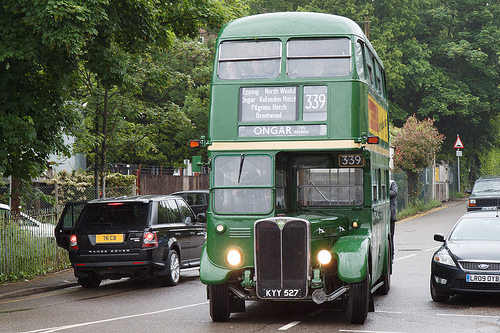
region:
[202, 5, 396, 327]
The double decker bus is green.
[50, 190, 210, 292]
The Range Rover to the left of the bus has its door open.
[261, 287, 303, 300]
The plate on the grill of the bus has the letters KYY 527 on it.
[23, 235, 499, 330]
White lines are painted on the wet pavement.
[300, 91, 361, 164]
The numbers 339 can be seen on the front of the bus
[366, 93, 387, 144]
A yellow sign is painted on the upper level of the side of the bus.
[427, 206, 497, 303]
The car to the right of the bus is black.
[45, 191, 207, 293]
The SUV to the left of the bus is black.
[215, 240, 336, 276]
The bus has its headlights turned on.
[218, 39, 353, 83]
Passengers can be faintly seen through the second level windows of the bus.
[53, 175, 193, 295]
Black sport utility vehicle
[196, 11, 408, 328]
Green double decker bus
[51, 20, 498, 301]
Traffic on a street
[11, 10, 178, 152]
Tall green trees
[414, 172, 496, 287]
Line of vehicles in traffic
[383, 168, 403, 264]
Person standing in street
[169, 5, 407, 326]
Green bus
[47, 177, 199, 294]
Parked SUV with door open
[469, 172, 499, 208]
SUV in traffic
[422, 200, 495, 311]
Black car in traffic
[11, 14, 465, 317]
a large double decker bus on the street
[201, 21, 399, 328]
an old fashioned green city bus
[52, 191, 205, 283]
a black suv with an open door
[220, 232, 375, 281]
two bright headlights on a bus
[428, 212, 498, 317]
a black car parked on street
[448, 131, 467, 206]
a red and white street sign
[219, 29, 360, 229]
the front windows of a bus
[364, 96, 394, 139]
a yellow sign on the side of a bus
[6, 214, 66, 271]
a metal fence on the side of the street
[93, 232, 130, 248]
a yellow registration plate for a vehicle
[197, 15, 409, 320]
a double decker bus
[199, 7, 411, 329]
a green bus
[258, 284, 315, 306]
black with white letters and numbers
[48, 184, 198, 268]
a car with the door open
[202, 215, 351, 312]
two lights on, on the bus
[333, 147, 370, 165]
bus number 339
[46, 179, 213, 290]
a car parked on the side of the road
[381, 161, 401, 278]
a person hanging on to the back of the bus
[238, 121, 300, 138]
the word ongar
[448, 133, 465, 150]
a red and white triangle sign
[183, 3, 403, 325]
a green bus on a street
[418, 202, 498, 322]
a car on a street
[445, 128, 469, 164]
a sign on a pole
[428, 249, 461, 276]
a headlight on a car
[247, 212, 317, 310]
the front grill of a bus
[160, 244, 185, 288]
a wheel on a car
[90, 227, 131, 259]
a licence plate on the rear of a car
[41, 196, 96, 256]
a open door on a car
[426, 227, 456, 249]
a side rear view mirror on a car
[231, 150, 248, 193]
a windshield wiper on a bus